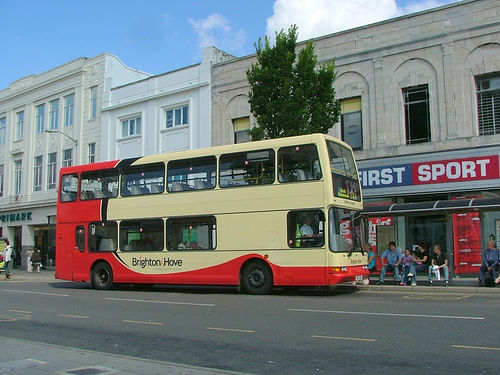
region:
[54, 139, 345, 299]
red and tan double deck bus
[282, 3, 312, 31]
white clouds in blue sky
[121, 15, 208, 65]
white clouds in blue sky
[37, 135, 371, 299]
bus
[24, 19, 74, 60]
white clouds in blue sky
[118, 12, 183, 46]
white clouds in blue sky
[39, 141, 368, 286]
double deck tan and red bus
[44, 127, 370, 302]
double deck bus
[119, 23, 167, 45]
white clouds in blue sky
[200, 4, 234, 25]
white clouds in blue sky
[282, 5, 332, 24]
white clouds in blue sky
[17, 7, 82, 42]
white clouds in blue sky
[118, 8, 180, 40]
white clouds in blue sky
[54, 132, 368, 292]
bus is red and white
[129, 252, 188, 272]
black letters on bus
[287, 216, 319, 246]
person driving the bus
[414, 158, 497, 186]
white letters on sign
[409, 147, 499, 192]
part of sign is red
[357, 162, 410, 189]
part of sign is blue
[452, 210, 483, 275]
the sign is red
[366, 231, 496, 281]
people are sitting down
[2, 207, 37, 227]
green letters on building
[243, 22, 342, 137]
tree beside the bus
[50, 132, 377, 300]
red and tan double deck bus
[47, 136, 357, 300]
double deck bus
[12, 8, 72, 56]
white clouds in blue sky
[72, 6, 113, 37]
white clouds in blue sky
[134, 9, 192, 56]
white clouds in blue sky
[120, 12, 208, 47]
white clouds in blue sky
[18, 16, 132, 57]
white clouds in blue sky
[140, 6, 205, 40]
white clouds in blue sky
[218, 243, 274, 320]
small black tire of bus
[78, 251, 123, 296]
small black tire on bus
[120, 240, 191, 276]
Brighton Hove can be read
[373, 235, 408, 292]
man sitting in shirt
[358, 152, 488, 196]
FIRST SPORT can be read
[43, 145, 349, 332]
red and creme bus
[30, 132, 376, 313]
large double decker bus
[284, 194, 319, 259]
man is driving bus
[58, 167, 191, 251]
lots of windows on bus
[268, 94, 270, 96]
A green leaf on a plant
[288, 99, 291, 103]
A green leaf on a plant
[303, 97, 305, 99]
A green leaf on a plant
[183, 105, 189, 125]
A window on a building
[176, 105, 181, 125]
A window on a building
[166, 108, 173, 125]
A window on a building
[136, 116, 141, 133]
A window on a building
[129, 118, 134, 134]
A window on a building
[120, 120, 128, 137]
A window on a building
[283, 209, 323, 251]
Window on a bus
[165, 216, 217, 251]
Window on a bus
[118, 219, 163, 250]
Window on a bus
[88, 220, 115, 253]
Window on a bus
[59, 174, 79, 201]
Window on a bus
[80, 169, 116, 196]
Window on a bus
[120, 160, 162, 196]
Window on a bus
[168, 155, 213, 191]
Window on a bus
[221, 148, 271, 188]
Window on a bus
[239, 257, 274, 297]
Tire of a bus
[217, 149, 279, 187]
window on a double decker